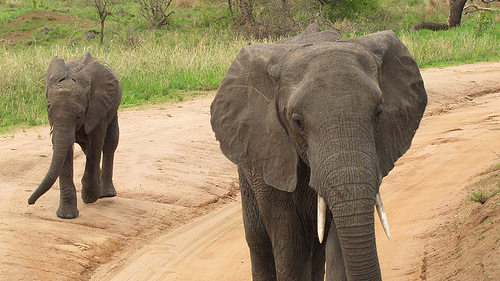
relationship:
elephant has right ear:
[209, 27, 427, 278] [212, 43, 300, 191]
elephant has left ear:
[209, 27, 427, 278] [355, 31, 427, 182]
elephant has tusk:
[209, 27, 427, 278] [316, 194, 327, 242]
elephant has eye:
[209, 27, 427, 278] [292, 118, 303, 129]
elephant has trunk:
[29, 53, 121, 218] [27, 103, 78, 203]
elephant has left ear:
[29, 53, 121, 218] [81, 55, 120, 136]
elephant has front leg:
[209, 27, 427, 278] [250, 160, 311, 280]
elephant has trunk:
[209, 27, 427, 278] [312, 113, 382, 279]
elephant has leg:
[209, 27, 427, 278] [242, 173, 275, 280]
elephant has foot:
[29, 53, 121, 218] [56, 198, 79, 217]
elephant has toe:
[29, 53, 121, 218] [66, 211, 74, 219]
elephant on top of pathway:
[209, 27, 427, 278] [1, 59, 499, 275]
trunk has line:
[312, 113, 382, 279] [312, 150, 378, 181]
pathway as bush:
[1, 59, 499, 275] [229, 1, 320, 37]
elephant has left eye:
[209, 27, 427, 278] [376, 107, 384, 118]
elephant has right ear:
[29, 53, 121, 218] [43, 56, 70, 89]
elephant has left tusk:
[209, 27, 427, 278] [375, 190, 392, 238]